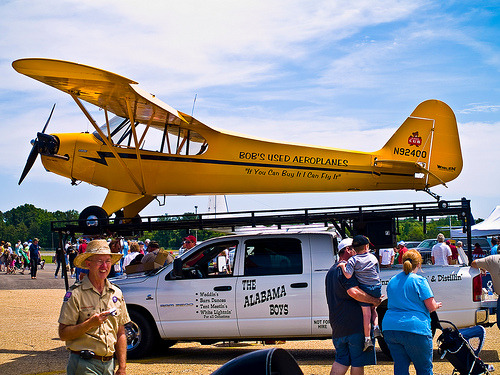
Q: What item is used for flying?
A: A airplane.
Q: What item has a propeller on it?
A: A airplane.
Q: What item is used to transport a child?
A: A stroller.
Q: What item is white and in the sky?
A: A cloud.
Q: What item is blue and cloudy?
A: The sky.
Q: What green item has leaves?
A: A tree.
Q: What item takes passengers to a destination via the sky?
A: A plane.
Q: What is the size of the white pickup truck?
A: Lareg.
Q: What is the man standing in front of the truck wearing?
A: A cowboy hat.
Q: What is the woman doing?
A: Pushing a stroller.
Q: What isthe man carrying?
A: A child.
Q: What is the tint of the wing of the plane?
A: Yellow.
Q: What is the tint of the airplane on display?
A: Yellow.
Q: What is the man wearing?
A: A straw hat.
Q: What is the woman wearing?
A: A blue shirt.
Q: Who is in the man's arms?
A: Little boy.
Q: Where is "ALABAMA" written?
A: On side of white truck.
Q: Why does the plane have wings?
A: To be able to fly.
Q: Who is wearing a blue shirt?
A: Woman on right.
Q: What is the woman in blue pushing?
A: Baby stroller.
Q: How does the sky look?
A: Blue with clouds.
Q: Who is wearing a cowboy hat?
A: Man on left.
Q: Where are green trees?
A: In the far distance.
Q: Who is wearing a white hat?
A: Man holding a kid.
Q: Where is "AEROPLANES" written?
A: On side of plane.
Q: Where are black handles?
A: On truck doors.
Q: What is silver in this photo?
A: Truck.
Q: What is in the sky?
A: Clouds.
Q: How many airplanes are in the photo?
A: One.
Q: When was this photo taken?
A: Daytime.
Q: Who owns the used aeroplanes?
A: Bob.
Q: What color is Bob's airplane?
A: Yellow.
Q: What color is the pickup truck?
A: White.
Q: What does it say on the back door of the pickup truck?
A: The Alabama Boys.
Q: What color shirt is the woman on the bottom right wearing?
A: Blue.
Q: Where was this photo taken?
A: At an outdoor festival.